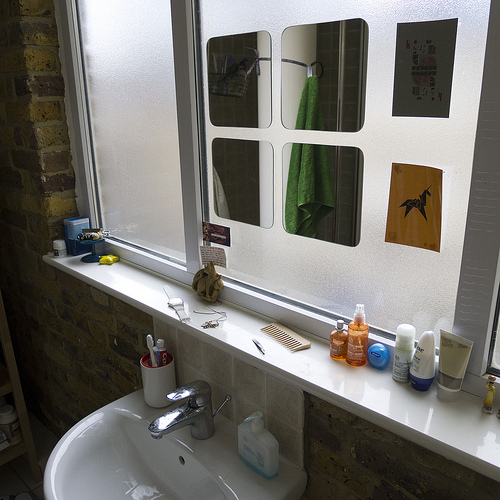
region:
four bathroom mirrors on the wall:
[205, 15, 370, 247]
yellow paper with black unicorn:
[383, 158, 446, 254]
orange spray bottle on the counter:
[346, 302, 369, 369]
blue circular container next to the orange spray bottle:
[366, 341, 390, 368]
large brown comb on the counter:
[258, 319, 313, 352]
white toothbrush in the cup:
[143, 330, 160, 370]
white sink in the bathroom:
[39, 380, 308, 498]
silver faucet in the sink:
[145, 380, 232, 446]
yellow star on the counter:
[98, 250, 120, 265]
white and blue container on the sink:
[233, 408, 283, 480]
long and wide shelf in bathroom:
[32, 220, 497, 462]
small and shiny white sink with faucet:
[47, 360, 307, 495]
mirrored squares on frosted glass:
[195, 0, 485, 351]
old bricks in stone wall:
[2, 2, 147, 492]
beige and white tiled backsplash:
[151, 320, 302, 461]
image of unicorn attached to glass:
[382, 156, 442, 251]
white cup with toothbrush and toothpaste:
[135, 327, 177, 407]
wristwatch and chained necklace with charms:
[155, 270, 232, 330]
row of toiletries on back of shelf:
[322, 301, 492, 408]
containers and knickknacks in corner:
[50, 203, 120, 268]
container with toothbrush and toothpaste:
[140, 333, 176, 405]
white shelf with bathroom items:
[42, 251, 497, 481]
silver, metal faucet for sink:
[147, 380, 229, 445]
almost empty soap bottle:
[237, 409, 279, 476]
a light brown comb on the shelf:
[262, 322, 312, 352]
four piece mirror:
[204, 19, 372, 244]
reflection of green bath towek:
[284, 70, 334, 232]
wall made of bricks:
[0, 0, 498, 497]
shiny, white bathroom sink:
[47, 391, 304, 498]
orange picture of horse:
[385, 160, 442, 250]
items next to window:
[316, 300, 478, 437]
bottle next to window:
[405, 327, 441, 389]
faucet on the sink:
[145, 381, 225, 463]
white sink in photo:
[91, 445, 162, 489]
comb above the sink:
[257, 318, 312, 360]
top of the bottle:
[346, 295, 375, 326]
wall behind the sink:
[308, 427, 362, 476]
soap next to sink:
[221, 394, 291, 478]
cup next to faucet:
[120, 332, 179, 404]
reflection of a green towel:
[285, 51, 343, 113]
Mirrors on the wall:
[206, 17, 369, 247]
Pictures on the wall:
[383, 17, 460, 254]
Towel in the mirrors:
[284, 74, 336, 239]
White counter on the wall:
[42, 251, 499, 480]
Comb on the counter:
[259, 319, 311, 352]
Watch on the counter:
[161, 277, 192, 324]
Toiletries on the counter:
[331, 302, 498, 414]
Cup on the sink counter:
[138, 352, 178, 408]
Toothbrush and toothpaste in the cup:
[144, 331, 168, 367]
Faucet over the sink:
[146, 378, 216, 442]